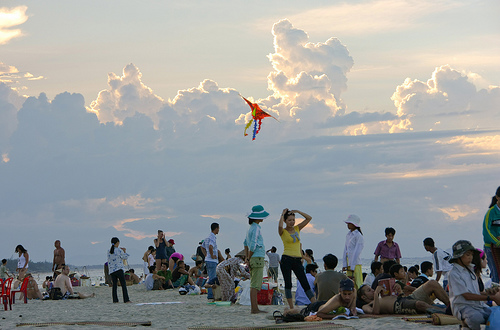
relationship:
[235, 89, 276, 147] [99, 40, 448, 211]
kite in sky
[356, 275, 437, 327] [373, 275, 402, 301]
guy reading a book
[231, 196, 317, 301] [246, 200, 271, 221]
girl with hat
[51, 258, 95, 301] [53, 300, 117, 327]
man sitting on sand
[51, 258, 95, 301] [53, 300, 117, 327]
man on sand